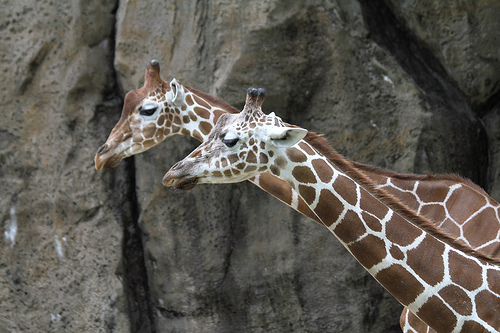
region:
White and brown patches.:
[327, 187, 380, 244]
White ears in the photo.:
[271, 124, 308, 149]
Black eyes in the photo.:
[220, 134, 236, 146]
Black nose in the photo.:
[93, 144, 109, 156]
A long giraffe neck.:
[283, 180, 387, 255]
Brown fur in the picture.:
[347, 166, 369, 186]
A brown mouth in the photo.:
[165, 175, 198, 189]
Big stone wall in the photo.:
[30, 47, 75, 149]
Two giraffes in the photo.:
[93, 59, 497, 311]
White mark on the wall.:
[5, 209, 18, 244]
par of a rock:
[218, 228, 278, 308]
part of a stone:
[246, 269, 300, 321]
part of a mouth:
[146, 153, 198, 212]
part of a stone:
[191, 220, 246, 289]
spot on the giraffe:
[381, 219, 417, 240]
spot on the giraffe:
[338, 213, 360, 243]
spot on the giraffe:
[434, 288, 464, 308]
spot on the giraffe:
[444, 189, 475, 211]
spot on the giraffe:
[301, 188, 312, 192]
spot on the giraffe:
[391, 277, 420, 303]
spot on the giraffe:
[387, 245, 403, 262]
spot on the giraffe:
[295, 170, 317, 184]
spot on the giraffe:
[456, 315, 486, 329]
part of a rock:
[203, 211, 240, 223]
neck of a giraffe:
[365, 238, 405, 282]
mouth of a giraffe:
[223, 177, 235, 193]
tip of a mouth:
[173, 167, 175, 179]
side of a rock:
[129, 252, 147, 282]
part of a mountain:
[125, 173, 240, 300]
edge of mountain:
[71, 153, 87, 202]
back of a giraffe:
[404, 234, 439, 247]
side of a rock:
[114, 223, 115, 248]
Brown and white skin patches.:
[330, 189, 386, 244]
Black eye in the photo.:
[224, 137, 241, 147]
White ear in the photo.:
[270, 123, 308, 147]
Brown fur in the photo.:
[341, 152, 362, 179]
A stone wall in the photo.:
[2, 7, 80, 235]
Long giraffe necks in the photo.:
[292, 159, 496, 331]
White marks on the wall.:
[1, 211, 21, 246]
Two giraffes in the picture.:
[95, 72, 497, 330]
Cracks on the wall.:
[117, 182, 154, 295]